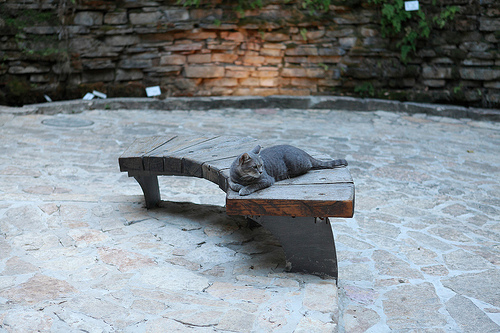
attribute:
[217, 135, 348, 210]
cat — grey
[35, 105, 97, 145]
cover — man hole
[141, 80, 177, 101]
sign — white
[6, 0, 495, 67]
plants — green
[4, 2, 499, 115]
wall — stone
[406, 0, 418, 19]
sign — white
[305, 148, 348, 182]
tail — grey, cat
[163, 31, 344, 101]
patch — small, sun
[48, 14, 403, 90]
wall — old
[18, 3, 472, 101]
wall — stone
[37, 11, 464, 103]
wall — brick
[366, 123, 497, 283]
walkway — stone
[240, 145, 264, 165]
ears — perked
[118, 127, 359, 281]
bench — wood, wooden, curved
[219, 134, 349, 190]
cat — grey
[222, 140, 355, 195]
cat — grey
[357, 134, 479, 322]
street — cobbled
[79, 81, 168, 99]
pieces — little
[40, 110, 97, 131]
cover — Manhole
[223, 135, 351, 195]
cat — grey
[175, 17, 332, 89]
light — artificial